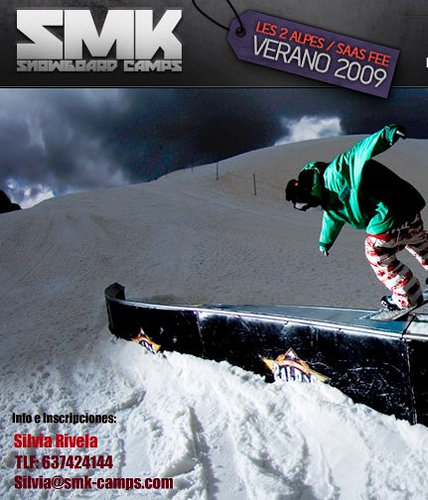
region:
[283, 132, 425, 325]
Snowboarder riding a rail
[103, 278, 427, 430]
Metal rail for snowboarding tricks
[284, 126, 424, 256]
Snowboarder wearing green jacket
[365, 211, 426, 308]
Red and white striped snowboard pants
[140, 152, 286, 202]
Fence line along the snow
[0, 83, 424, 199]
Stormy looking sky with clouds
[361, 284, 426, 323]
Nose of snowboard on rail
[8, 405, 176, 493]
Contact information for snowboard camp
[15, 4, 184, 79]
Snowboard camp logo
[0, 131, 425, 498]
Ground covered with snow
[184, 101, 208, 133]
part of a cloud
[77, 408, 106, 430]
part of a graphic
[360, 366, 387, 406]
part of a board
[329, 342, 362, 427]
part of a board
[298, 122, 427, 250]
The jacket is light green.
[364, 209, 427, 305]
The pants have red and white stripes.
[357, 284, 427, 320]
The person is on a snowboard.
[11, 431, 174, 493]
The letters are red.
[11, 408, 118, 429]
The letters are black.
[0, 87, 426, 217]
The sky is dark and cloudy.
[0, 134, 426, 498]
The hill is covered in snow.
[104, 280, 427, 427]
The platform is black.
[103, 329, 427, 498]
The snow here is very bright.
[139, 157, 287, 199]
Fencing runs along the hill.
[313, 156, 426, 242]
green jacket on person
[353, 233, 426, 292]
red and white ski pants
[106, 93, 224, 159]
greyish black clouds in sky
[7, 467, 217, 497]
silvia@smk-camps.com website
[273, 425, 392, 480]
white powdery snow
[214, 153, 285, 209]
metal snow fence in distance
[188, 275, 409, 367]
black ski ramp on right side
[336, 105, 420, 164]
extended arm in green ski jacket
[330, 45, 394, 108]
2009 written on tag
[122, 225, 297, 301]
lots of tracks in snow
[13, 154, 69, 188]
this is the sky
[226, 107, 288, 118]
the sky is blue in color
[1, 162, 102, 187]
the sky has clouds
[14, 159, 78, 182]
the clouds are white in color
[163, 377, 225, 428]
this is the ground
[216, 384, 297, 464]
the ground is full of snow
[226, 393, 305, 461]
the snow is white in color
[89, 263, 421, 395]
this is an object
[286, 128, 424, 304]
this is a person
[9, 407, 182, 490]
these are some writings